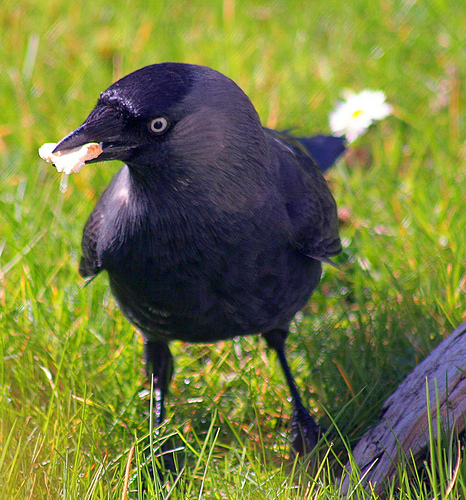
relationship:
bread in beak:
[39, 140, 104, 178] [50, 103, 135, 166]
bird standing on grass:
[54, 61, 346, 479] [1, 2, 464, 498]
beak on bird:
[50, 103, 135, 166] [54, 61, 346, 479]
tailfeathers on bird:
[281, 123, 347, 178] [54, 61, 346, 479]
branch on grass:
[338, 319, 465, 498] [1, 2, 464, 498]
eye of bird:
[151, 117, 167, 134] [54, 61, 346, 479]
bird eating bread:
[54, 61, 346, 479] [39, 140, 104, 178]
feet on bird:
[266, 329, 330, 481] [54, 61, 346, 479]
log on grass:
[339, 320, 465, 498] [1, 2, 464, 498]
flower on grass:
[326, 86, 391, 141] [1, 2, 464, 498]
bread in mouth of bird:
[39, 140, 104, 178] [54, 61, 346, 479]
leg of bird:
[140, 335, 181, 486] [54, 61, 346, 479]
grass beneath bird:
[1, 2, 464, 498] [54, 61, 346, 479]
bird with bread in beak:
[54, 61, 346, 479] [50, 103, 135, 166]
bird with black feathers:
[54, 61, 346, 479] [80, 61, 352, 344]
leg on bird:
[140, 335, 181, 486] [54, 61, 346, 479]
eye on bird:
[151, 117, 167, 134] [54, 61, 346, 479]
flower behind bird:
[326, 86, 395, 147] [54, 61, 346, 479]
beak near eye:
[50, 103, 135, 166] [151, 117, 167, 134]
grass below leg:
[1, 2, 464, 498] [140, 335, 181, 486]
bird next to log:
[54, 61, 346, 479] [339, 320, 465, 498]